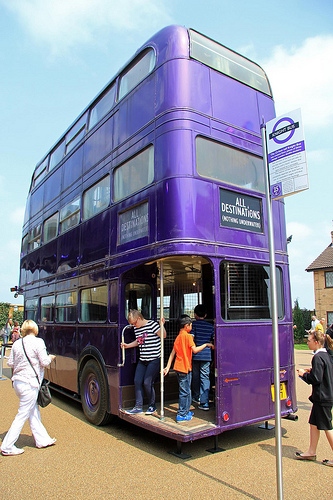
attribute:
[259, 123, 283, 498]
pole — thin, silver, metal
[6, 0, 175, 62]
cloud — white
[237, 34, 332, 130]
cloud — white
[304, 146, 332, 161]
cloud — white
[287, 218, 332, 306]
cloud — white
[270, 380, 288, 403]
license plate — yellow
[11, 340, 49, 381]
shirt — white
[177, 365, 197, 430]
pants — long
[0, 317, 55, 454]
lady — blonde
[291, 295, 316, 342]
bushes — tall, green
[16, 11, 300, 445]
building — two story, tan, brick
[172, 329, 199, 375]
shirt — orange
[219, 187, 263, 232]
sign — black, white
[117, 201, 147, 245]
sign — white, black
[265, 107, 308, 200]
sign — white, black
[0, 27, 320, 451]
bus — shiny, purple, triple, decker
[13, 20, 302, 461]
bus — purple, triple deck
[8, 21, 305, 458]
passenger bus — purple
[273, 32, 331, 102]
clouds — white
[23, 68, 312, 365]
bus — purple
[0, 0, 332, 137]
clouds — white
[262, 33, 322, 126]
clouds — white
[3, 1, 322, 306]
sky — blue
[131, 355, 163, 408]
pants — long, blue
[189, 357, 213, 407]
pants — long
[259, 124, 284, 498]
post — sign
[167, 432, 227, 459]
bars — metal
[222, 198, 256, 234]
letters — white